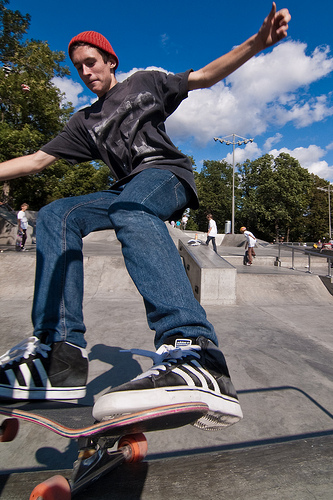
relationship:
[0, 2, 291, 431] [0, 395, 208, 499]
boy with skateboard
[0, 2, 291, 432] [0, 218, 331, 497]
boy at skatepark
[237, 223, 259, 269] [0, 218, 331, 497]
boy at skatepark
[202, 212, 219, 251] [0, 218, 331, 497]
man at skatepark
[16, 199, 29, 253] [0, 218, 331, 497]
man at skatepark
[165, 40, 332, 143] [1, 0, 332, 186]
cloud in sky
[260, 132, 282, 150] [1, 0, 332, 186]
cloud in sky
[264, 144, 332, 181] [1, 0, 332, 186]
cloud in sky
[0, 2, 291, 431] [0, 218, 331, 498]
boy skates in park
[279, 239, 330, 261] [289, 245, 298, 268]
metal rail on pole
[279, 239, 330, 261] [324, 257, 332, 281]
metal rail on pole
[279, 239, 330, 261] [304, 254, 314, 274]
metal rail on pole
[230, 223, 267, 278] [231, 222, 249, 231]
boy with helmet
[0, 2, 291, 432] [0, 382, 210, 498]
boy on skateboard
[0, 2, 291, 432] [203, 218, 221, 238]
boy wearing white t-shirt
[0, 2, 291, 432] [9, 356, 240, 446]
boy holding skateboard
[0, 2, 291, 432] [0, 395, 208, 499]
boy riding skateboard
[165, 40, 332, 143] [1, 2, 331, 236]
cloud in sky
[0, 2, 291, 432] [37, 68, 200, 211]
boy wearing tee shirt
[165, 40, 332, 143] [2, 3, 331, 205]
cloud in sky